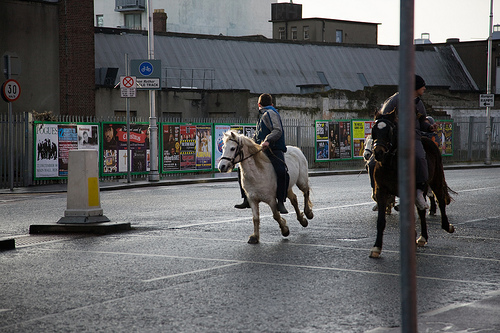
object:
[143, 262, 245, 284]
line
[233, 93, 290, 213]
person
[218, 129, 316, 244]
horse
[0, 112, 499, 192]
fence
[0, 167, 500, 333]
road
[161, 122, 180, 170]
signs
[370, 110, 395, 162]
head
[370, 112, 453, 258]
horse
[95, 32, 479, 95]
awning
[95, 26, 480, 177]
building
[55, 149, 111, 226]
statue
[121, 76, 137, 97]
sign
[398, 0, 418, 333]
pole